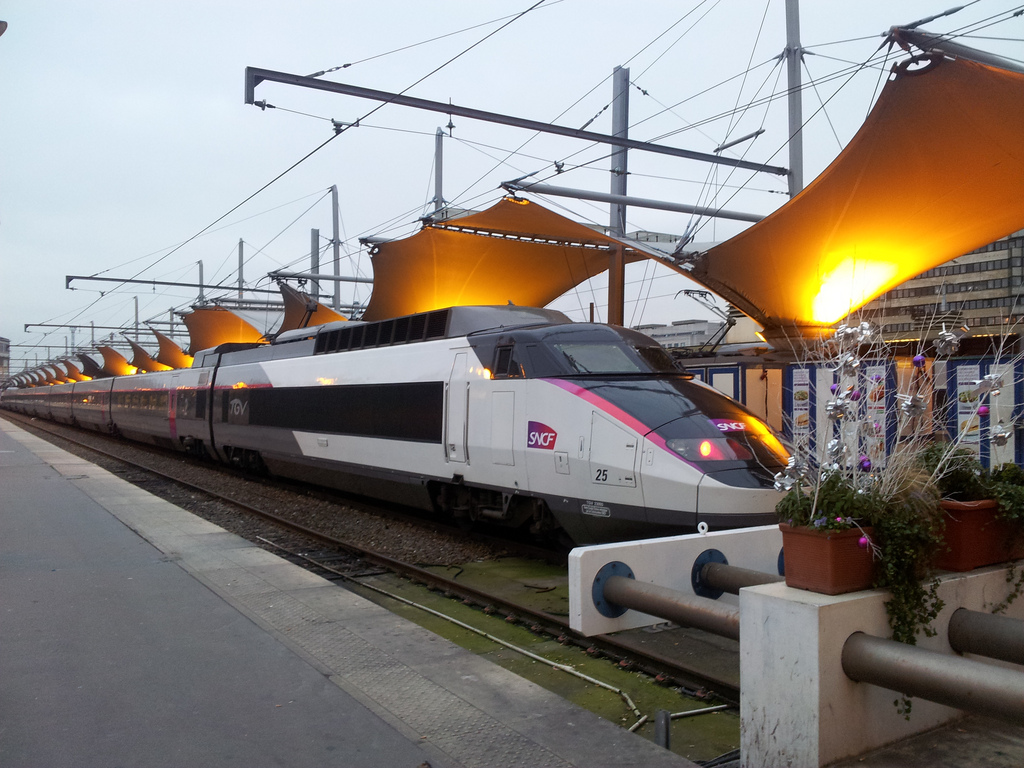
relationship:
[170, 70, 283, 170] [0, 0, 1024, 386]
clouds in clouds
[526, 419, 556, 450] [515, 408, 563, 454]
sign on sign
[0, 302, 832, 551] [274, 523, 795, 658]
car on tracks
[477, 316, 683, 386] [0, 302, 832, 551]
window on car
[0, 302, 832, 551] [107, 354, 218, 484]
car has passenger car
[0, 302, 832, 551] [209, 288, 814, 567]
car has engine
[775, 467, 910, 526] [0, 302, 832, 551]
plants near car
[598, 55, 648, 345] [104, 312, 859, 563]
pole behind a train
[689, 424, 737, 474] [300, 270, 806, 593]
light on a train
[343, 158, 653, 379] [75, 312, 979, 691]
canopy behind a train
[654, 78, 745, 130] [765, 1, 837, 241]
wire on pole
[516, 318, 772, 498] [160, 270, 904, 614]
trim on train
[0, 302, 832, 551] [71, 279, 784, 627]
car on train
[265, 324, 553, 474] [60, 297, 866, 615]
side of train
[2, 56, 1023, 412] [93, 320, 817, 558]
canopy next to train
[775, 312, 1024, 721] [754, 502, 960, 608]
plants in a box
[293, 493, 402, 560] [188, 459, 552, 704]
gravel on tracks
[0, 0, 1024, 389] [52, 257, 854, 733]
wire above train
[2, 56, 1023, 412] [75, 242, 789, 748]
canopy over train platform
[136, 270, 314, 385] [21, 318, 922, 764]
canopy over train platform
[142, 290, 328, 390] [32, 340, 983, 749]
canopy over train platform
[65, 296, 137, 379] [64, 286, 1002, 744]
canopy over train platform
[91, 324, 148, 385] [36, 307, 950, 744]
canopy over train platform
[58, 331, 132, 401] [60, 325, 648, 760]
canopy over train platform